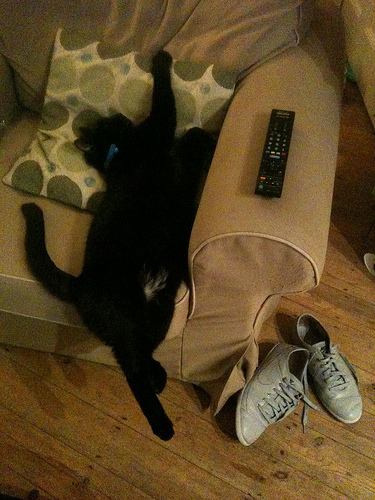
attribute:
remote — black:
[252, 104, 299, 203]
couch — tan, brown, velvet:
[1, 3, 351, 423]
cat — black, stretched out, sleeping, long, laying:
[18, 39, 218, 453]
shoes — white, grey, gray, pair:
[230, 311, 367, 451]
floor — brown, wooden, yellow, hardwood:
[5, 352, 370, 500]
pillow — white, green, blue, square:
[7, 22, 243, 214]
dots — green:
[9, 25, 240, 213]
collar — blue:
[102, 141, 125, 166]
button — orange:
[259, 173, 268, 181]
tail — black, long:
[17, 197, 81, 311]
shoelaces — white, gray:
[254, 347, 353, 432]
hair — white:
[138, 268, 175, 304]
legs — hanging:
[97, 338, 189, 448]